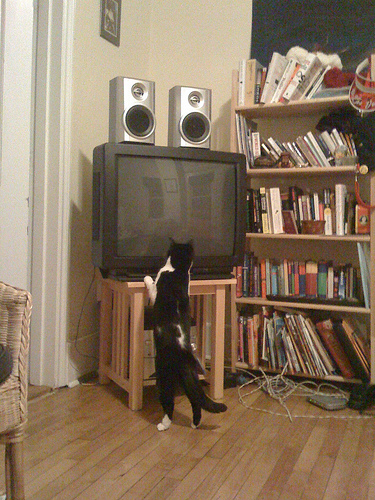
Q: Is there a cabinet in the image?
A: No, there are no cabinets.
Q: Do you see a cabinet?
A: No, there are no cabinets.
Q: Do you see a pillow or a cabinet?
A: No, there are no cabinets or pillows.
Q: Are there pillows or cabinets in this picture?
A: No, there are no cabinets or pillows.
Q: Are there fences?
A: No, there are no fences.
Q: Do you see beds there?
A: No, there are no beds.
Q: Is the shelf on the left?
A: No, the shelf is on the right of the image.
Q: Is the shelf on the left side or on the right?
A: The shelf is on the right of the image.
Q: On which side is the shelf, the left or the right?
A: The shelf is on the right of the image.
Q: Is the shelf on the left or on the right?
A: The shelf is on the right of the image.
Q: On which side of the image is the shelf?
A: The shelf is on the right of the image.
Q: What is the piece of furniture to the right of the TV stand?
A: The piece of furniture is a shelf.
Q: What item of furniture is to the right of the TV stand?
A: The piece of furniture is a shelf.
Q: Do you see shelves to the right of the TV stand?
A: Yes, there is a shelf to the right of the TV stand.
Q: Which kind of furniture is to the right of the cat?
A: The piece of furniture is a shelf.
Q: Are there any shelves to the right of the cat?
A: Yes, there is a shelf to the right of the cat.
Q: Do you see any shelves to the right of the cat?
A: Yes, there is a shelf to the right of the cat.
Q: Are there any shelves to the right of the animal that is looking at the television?
A: Yes, there is a shelf to the right of the cat.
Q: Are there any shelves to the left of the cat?
A: No, the shelf is to the right of the cat.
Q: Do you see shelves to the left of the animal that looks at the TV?
A: No, the shelf is to the right of the cat.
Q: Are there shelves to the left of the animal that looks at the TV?
A: No, the shelf is to the right of the cat.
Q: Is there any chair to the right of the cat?
A: No, there is a shelf to the right of the cat.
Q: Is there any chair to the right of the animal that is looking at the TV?
A: No, there is a shelf to the right of the cat.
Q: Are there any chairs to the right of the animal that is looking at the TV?
A: No, there is a shelf to the right of the cat.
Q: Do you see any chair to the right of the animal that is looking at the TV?
A: No, there is a shelf to the right of the cat.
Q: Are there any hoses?
A: No, there are no hoses.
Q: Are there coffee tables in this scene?
A: No, there are no coffee tables.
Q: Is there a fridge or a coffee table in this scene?
A: No, there are no coffee tables or refrigerators.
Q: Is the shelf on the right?
A: Yes, the shelf is on the right of the image.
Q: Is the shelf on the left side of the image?
A: No, the shelf is on the right of the image.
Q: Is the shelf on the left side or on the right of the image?
A: The shelf is on the right of the image.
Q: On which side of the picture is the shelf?
A: The shelf is on the right of the image.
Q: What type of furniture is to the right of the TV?
A: The piece of furniture is a shelf.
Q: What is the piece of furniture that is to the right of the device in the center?
A: The piece of furniture is a shelf.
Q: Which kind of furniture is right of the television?
A: The piece of furniture is a shelf.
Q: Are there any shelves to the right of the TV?
A: Yes, there is a shelf to the right of the TV.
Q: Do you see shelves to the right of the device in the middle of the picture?
A: Yes, there is a shelf to the right of the TV.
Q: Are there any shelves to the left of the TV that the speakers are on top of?
A: No, the shelf is to the right of the TV.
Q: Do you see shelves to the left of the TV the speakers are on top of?
A: No, the shelf is to the right of the TV.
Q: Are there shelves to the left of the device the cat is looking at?
A: No, the shelf is to the right of the TV.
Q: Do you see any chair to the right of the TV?
A: No, there is a shelf to the right of the TV.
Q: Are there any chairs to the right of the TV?
A: No, there is a shelf to the right of the TV.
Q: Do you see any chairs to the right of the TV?
A: No, there is a shelf to the right of the TV.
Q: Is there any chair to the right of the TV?
A: No, there is a shelf to the right of the TV.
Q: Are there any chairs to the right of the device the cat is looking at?
A: No, there is a shelf to the right of the TV.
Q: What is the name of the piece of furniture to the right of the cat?
A: The piece of furniture is a shelf.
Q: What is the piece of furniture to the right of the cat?
A: The piece of furniture is a shelf.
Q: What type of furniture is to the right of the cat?
A: The piece of furniture is a shelf.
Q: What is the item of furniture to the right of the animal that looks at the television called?
A: The piece of furniture is a shelf.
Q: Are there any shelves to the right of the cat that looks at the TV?
A: Yes, there is a shelf to the right of the cat.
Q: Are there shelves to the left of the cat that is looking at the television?
A: No, the shelf is to the right of the cat.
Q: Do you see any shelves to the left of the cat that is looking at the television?
A: No, the shelf is to the right of the cat.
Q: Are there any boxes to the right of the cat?
A: No, there is a shelf to the right of the cat.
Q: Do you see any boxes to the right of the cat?
A: No, there is a shelf to the right of the cat.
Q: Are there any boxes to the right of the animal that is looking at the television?
A: No, there is a shelf to the right of the cat.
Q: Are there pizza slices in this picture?
A: No, there are no pizza slices.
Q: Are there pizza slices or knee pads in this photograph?
A: No, there are no pizza slices or knee pads.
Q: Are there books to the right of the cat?
A: Yes, there is a book to the right of the cat.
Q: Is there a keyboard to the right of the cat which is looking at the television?
A: No, there is a book to the right of the cat.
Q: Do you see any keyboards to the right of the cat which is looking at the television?
A: No, there is a book to the right of the cat.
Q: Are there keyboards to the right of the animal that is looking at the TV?
A: No, there is a book to the right of the cat.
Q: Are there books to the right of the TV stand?
A: Yes, there is a book to the right of the TV stand.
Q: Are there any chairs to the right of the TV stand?
A: No, there is a book to the right of the TV stand.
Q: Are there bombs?
A: No, there are no bombs.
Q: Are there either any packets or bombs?
A: No, there are no bombs or packets.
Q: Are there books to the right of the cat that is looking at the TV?
A: Yes, there is a book to the right of the cat.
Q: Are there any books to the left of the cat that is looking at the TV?
A: No, the book is to the right of the cat.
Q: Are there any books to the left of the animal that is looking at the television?
A: No, the book is to the right of the cat.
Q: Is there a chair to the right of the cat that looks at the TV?
A: No, there is a book to the right of the cat.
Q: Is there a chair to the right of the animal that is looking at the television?
A: No, there is a book to the right of the cat.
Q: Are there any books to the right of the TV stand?
A: Yes, there is a book to the right of the TV stand.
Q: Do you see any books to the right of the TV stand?
A: Yes, there is a book to the right of the TV stand.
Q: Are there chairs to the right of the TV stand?
A: No, there is a book to the right of the TV stand.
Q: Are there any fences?
A: No, there are no fences.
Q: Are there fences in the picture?
A: No, there are no fences.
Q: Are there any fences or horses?
A: No, there are no fences or horses.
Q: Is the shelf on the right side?
A: Yes, the shelf is on the right of the image.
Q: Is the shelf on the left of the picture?
A: No, the shelf is on the right of the image.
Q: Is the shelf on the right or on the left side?
A: The shelf is on the right of the image.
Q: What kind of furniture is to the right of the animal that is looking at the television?
A: The piece of furniture is a shelf.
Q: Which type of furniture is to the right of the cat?
A: The piece of furniture is a shelf.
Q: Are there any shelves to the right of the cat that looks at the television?
A: Yes, there is a shelf to the right of the cat.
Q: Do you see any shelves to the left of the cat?
A: No, the shelf is to the right of the cat.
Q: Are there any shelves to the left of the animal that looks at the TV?
A: No, the shelf is to the right of the cat.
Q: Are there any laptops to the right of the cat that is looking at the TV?
A: No, there is a shelf to the right of the cat.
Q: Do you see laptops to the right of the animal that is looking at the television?
A: No, there is a shelf to the right of the cat.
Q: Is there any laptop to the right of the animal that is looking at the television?
A: No, there is a shelf to the right of the cat.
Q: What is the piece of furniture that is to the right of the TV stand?
A: The piece of furniture is a shelf.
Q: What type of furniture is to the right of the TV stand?
A: The piece of furniture is a shelf.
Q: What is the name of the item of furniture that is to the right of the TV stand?
A: The piece of furniture is a shelf.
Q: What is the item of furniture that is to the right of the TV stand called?
A: The piece of furniture is a shelf.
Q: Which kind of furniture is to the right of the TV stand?
A: The piece of furniture is a shelf.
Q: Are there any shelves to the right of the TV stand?
A: Yes, there is a shelf to the right of the TV stand.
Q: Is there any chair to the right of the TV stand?
A: No, there is a shelf to the right of the TV stand.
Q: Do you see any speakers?
A: Yes, there are speakers.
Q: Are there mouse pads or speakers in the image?
A: Yes, there are speakers.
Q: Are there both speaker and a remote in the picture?
A: No, there are speakers but no remote controls.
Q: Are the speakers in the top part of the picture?
A: Yes, the speakers are in the top of the image.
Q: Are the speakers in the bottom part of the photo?
A: No, the speakers are in the top of the image.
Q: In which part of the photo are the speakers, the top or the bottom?
A: The speakers are in the top of the image.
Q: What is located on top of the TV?
A: The speakers are on top of the TV.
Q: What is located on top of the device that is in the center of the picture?
A: The speakers are on top of the TV.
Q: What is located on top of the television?
A: The speakers are on top of the TV.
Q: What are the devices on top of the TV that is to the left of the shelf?
A: The devices are speakers.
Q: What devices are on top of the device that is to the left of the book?
A: The devices are speakers.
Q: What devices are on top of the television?
A: The devices are speakers.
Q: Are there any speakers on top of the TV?
A: Yes, there are speakers on top of the TV.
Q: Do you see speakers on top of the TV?
A: Yes, there are speakers on top of the TV.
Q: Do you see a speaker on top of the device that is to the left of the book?
A: Yes, there are speakers on top of the TV.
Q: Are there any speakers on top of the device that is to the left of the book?
A: Yes, there are speakers on top of the TV.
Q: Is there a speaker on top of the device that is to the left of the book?
A: Yes, there are speakers on top of the TV.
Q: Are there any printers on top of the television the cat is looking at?
A: No, there are speakers on top of the TV.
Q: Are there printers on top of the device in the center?
A: No, there are speakers on top of the TV.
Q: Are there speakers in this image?
A: Yes, there are speakers.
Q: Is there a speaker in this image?
A: Yes, there are speakers.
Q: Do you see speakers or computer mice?
A: Yes, there are speakers.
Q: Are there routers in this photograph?
A: No, there are no routers.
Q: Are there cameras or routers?
A: No, there are no routers or cameras.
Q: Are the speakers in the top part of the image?
A: Yes, the speakers are in the top of the image.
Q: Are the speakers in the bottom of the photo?
A: No, the speakers are in the top of the image.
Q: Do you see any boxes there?
A: No, there are no boxes.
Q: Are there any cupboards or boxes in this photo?
A: No, there are no boxes or cupboards.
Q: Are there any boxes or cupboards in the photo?
A: No, there are no boxes or cupboards.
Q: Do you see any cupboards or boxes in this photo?
A: No, there are no boxes or cupboards.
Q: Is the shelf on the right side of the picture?
A: Yes, the shelf is on the right of the image.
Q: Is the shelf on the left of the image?
A: No, the shelf is on the right of the image.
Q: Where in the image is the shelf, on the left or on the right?
A: The shelf is on the right of the image.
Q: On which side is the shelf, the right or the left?
A: The shelf is on the right of the image.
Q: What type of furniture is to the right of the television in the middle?
A: The piece of furniture is a shelf.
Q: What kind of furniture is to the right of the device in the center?
A: The piece of furniture is a shelf.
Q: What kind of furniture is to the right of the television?
A: The piece of furniture is a shelf.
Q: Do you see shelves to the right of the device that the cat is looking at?
A: Yes, there is a shelf to the right of the TV.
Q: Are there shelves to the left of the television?
A: No, the shelf is to the right of the television.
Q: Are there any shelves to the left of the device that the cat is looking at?
A: No, the shelf is to the right of the television.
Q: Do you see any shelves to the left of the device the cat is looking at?
A: No, the shelf is to the right of the television.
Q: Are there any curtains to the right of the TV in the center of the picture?
A: No, there is a shelf to the right of the television.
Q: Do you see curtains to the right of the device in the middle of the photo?
A: No, there is a shelf to the right of the television.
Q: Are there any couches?
A: No, there are no couches.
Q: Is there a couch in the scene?
A: No, there are no couches.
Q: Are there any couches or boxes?
A: No, there are no couches or boxes.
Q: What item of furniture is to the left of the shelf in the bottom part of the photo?
A: The piece of furniture is a TV stand.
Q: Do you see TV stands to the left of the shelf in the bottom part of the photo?
A: Yes, there is a TV stand to the left of the shelf.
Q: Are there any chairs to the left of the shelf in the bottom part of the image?
A: No, there is a TV stand to the left of the shelf.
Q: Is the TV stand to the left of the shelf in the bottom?
A: Yes, the TV stand is to the left of the shelf.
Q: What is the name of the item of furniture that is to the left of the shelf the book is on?
A: The piece of furniture is a TV stand.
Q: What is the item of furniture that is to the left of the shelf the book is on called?
A: The piece of furniture is a TV stand.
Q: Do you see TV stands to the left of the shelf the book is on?
A: Yes, there is a TV stand to the left of the shelf.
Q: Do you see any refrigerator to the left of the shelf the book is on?
A: No, there is a TV stand to the left of the shelf.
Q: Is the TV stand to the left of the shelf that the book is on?
A: Yes, the TV stand is to the left of the shelf.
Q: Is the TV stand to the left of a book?
A: Yes, the TV stand is to the left of a book.